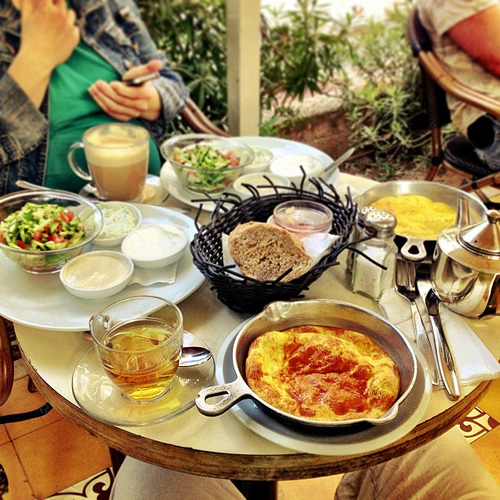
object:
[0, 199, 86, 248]
salad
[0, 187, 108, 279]
bowl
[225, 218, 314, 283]
bread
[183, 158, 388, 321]
basket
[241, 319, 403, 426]
omellette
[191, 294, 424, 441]
skillet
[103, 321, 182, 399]
tea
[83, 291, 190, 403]
cup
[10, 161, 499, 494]
table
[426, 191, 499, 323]
kettle